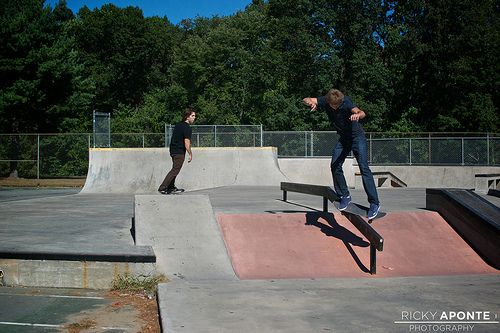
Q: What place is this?
A: It is a skate park.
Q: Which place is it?
A: It is a skate park.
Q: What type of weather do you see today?
A: It is clear.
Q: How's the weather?
A: It is clear.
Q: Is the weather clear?
A: Yes, it is clear.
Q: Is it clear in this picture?
A: Yes, it is clear.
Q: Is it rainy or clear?
A: It is clear.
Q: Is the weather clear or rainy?
A: It is clear.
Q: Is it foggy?
A: No, it is clear.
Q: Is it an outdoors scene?
A: Yes, it is outdoors.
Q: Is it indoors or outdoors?
A: It is outdoors.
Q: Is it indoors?
A: No, it is outdoors.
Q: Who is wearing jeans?
A: The boy is wearing jeans.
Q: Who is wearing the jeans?
A: The boy is wearing jeans.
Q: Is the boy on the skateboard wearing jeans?
A: Yes, the boy is wearing jeans.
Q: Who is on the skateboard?
A: The boy is on the skateboard.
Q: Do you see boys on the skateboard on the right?
A: Yes, there is a boy on the skateboard.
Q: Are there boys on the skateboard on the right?
A: Yes, there is a boy on the skateboard.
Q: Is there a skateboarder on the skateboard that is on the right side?
A: No, there is a boy on the skateboard.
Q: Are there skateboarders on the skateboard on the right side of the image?
A: No, there is a boy on the skateboard.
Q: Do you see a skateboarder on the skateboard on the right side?
A: No, there is a boy on the skateboard.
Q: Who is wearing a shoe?
A: The boy is wearing a shoe.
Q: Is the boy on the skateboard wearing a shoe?
A: Yes, the boy is wearing a shoe.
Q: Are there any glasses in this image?
A: No, there are no glasses.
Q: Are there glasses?
A: No, there are no glasses.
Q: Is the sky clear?
A: Yes, the sky is clear.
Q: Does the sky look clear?
A: Yes, the sky is clear.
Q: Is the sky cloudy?
A: No, the sky is clear.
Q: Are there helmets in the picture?
A: No, there are no helmets.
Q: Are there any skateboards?
A: Yes, there is a skateboard.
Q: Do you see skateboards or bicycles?
A: Yes, there is a skateboard.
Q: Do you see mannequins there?
A: No, there are no mannequins.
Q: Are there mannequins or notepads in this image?
A: No, there are no mannequins or notepads.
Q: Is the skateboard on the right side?
A: Yes, the skateboard is on the right of the image.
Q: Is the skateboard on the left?
A: No, the skateboard is on the right of the image.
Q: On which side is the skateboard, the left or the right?
A: The skateboard is on the right of the image.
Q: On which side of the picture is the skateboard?
A: The skateboard is on the right of the image.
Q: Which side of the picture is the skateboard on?
A: The skateboard is on the right of the image.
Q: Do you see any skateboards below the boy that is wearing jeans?
A: Yes, there is a skateboard below the boy.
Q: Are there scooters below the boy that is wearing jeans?
A: No, there is a skateboard below the boy.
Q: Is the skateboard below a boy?
A: Yes, the skateboard is below a boy.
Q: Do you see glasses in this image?
A: No, there are no glasses.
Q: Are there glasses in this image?
A: No, there are no glasses.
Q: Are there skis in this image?
A: No, there are no skis.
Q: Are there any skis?
A: No, there are no skis.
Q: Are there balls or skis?
A: No, there are no skis or balls.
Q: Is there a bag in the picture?
A: No, there are no bags.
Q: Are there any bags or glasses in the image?
A: No, there are no bags or glasses.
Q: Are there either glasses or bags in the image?
A: No, there are no bags or glasses.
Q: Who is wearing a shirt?
A: The boy is wearing a shirt.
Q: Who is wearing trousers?
A: The boy is wearing trousers.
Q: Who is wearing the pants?
A: The boy is wearing trousers.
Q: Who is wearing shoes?
A: The boy is wearing shoes.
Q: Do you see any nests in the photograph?
A: No, there are no nests.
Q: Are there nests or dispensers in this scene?
A: No, there are no nests or dispensers.